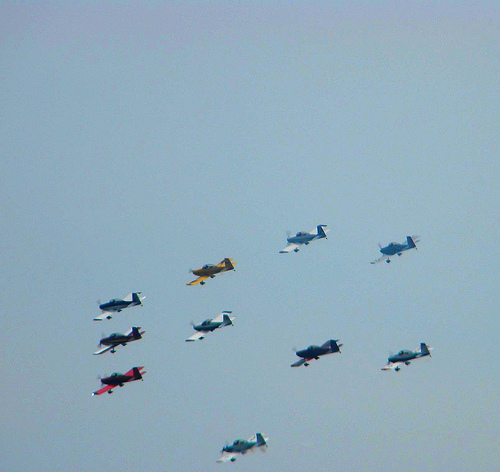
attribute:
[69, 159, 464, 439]
planes — black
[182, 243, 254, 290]
plane — yellow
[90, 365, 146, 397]
red plane — lead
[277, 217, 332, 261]
plane — small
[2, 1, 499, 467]
sky — blue, murkey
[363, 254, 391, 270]
wings — white